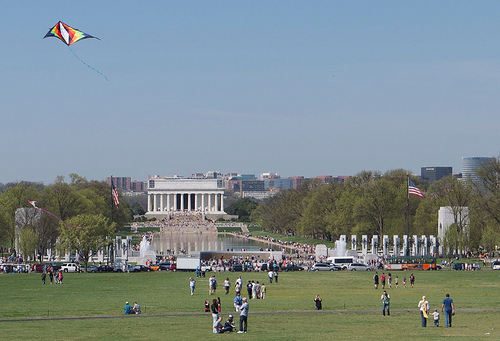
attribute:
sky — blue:
[4, 4, 493, 194]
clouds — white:
[208, 25, 309, 108]